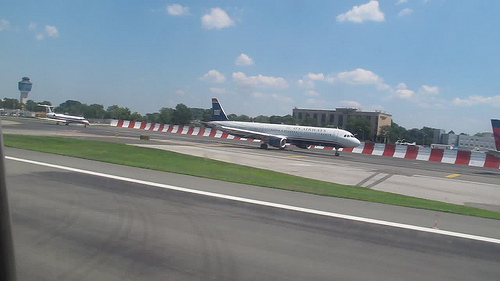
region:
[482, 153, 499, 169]
red stripe on wall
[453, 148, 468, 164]
red stripe on wall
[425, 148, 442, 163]
red stripe on wall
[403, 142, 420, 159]
red stripe on wall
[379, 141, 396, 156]
red stripe on wall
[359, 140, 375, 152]
red stripe on wall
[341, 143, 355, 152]
red stripe on wall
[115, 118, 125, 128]
red stripe on wall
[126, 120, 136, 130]
red stripe on wall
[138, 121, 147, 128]
red stripe on wall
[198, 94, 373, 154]
plane on the runway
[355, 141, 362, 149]
nose of the plane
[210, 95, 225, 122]
tail of the plane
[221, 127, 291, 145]
wing of the plane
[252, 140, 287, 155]
wheels of the plane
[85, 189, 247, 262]
the round way is concrete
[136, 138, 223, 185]
grass on the runway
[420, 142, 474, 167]
red and white pattern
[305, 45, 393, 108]
some clouds in sky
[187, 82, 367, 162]
An airplane on a runway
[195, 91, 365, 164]
An airplane on a runway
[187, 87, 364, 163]
An airplane on a runway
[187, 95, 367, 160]
An airplane on a runway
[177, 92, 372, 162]
An airplane on a runway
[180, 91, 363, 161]
An airplane on a runway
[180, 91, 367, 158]
An airplane on a runway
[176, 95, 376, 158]
An airplane on a runway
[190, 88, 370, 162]
An airplane on a runway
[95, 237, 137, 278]
White plane on the run way.